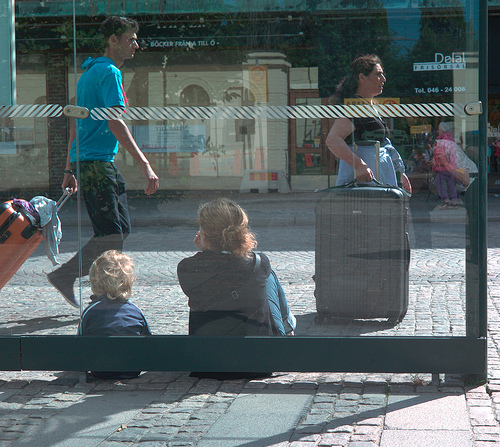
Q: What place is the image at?
A: It is at the street.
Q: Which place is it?
A: It is a street.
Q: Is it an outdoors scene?
A: Yes, it is outdoors.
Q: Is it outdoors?
A: Yes, it is outdoors.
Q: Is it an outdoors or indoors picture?
A: It is outdoors.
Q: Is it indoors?
A: No, it is outdoors.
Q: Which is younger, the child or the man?
A: The child is younger than the man.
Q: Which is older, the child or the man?
A: The man is older than the child.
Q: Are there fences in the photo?
A: No, there are no fences.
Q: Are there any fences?
A: No, there are no fences.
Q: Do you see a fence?
A: No, there are no fences.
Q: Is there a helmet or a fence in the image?
A: No, there are no fences or helmets.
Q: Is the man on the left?
A: Yes, the man is on the left of the image.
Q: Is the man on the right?
A: No, the man is on the left of the image.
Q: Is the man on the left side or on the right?
A: The man is on the left of the image.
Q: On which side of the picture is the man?
A: The man is on the left of the image.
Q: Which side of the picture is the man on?
A: The man is on the left of the image.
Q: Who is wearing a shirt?
A: The man is wearing a shirt.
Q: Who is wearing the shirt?
A: The man is wearing a shirt.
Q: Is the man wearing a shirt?
A: Yes, the man is wearing a shirt.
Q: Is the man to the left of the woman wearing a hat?
A: No, the man is wearing a shirt.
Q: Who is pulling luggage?
A: The man is pulling luggage.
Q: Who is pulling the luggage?
A: The man is pulling luggage.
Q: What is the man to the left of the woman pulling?
A: The man is pulling luggage.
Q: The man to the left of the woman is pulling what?
A: The man is pulling luggage.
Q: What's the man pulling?
A: The man is pulling luggage.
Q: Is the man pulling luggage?
A: Yes, the man is pulling luggage.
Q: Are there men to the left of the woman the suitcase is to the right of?
A: Yes, there is a man to the left of the woman.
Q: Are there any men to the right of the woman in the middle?
A: No, the man is to the left of the woman.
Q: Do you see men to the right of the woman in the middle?
A: No, the man is to the left of the woman.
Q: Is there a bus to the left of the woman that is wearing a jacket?
A: No, there is a man to the left of the woman.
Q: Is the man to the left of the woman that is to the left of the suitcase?
A: Yes, the man is to the left of the woman.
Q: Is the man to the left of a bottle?
A: No, the man is to the left of the woman.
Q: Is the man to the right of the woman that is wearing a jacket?
A: No, the man is to the left of the woman.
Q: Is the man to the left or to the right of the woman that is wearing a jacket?
A: The man is to the left of the woman.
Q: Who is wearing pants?
A: The man is wearing pants.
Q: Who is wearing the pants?
A: The man is wearing pants.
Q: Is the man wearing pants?
A: Yes, the man is wearing pants.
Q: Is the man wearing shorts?
A: No, the man is wearing pants.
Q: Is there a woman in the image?
A: Yes, there is a woman.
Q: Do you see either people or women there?
A: Yes, there is a woman.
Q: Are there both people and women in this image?
A: Yes, there are both a woman and people.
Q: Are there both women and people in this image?
A: Yes, there are both a woman and people.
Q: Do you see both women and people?
A: Yes, there are both a woman and people.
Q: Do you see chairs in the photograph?
A: No, there are no chairs.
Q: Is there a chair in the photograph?
A: No, there are no chairs.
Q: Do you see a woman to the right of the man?
A: Yes, there is a woman to the right of the man.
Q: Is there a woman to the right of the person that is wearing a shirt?
A: Yes, there is a woman to the right of the man.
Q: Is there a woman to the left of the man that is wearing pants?
A: No, the woman is to the right of the man.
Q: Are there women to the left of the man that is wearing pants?
A: No, the woman is to the right of the man.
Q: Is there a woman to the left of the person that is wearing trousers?
A: No, the woman is to the right of the man.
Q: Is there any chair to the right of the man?
A: No, there is a woman to the right of the man.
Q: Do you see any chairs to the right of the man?
A: No, there is a woman to the right of the man.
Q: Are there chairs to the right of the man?
A: No, there is a woman to the right of the man.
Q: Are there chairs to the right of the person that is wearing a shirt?
A: No, there is a woman to the right of the man.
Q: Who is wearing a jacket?
A: The woman is wearing a jacket.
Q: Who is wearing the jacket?
A: The woman is wearing a jacket.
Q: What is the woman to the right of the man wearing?
A: The woman is wearing a jacket.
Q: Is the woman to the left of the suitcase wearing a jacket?
A: Yes, the woman is wearing a jacket.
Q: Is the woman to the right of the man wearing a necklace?
A: No, the woman is wearing a jacket.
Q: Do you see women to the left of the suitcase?
A: Yes, there is a woman to the left of the suitcase.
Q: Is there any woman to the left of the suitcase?
A: Yes, there is a woman to the left of the suitcase.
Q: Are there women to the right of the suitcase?
A: No, the woman is to the left of the suitcase.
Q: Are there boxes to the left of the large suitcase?
A: No, there is a woman to the left of the suitcase.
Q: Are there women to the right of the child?
A: Yes, there is a woman to the right of the child.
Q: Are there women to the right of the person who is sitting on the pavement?
A: Yes, there is a woman to the right of the child.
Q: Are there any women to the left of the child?
A: No, the woman is to the right of the child.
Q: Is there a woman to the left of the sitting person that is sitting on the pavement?
A: No, the woman is to the right of the child.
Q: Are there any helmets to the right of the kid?
A: No, there is a woman to the right of the kid.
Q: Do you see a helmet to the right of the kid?
A: No, there is a woman to the right of the kid.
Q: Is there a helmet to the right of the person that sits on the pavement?
A: No, there is a woman to the right of the kid.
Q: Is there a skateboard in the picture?
A: No, there are no skateboards.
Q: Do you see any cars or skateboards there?
A: No, there are no skateboards or cars.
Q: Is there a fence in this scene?
A: No, there are no fences.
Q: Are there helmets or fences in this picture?
A: No, there are no fences or helmets.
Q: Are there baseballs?
A: No, there are no baseballs.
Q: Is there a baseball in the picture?
A: No, there are no baseballs.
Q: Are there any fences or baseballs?
A: No, there are no baseballs or fences.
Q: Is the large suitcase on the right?
A: Yes, the suitcase is on the right of the image.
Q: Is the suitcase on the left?
A: No, the suitcase is on the right of the image.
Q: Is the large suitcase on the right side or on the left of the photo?
A: The suitcase is on the right of the image.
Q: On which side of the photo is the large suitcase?
A: The suitcase is on the right of the image.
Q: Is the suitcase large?
A: Yes, the suitcase is large.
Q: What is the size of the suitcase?
A: The suitcase is large.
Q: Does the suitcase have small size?
A: No, the suitcase is large.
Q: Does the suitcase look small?
A: No, the suitcase is large.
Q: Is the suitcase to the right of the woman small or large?
A: The suitcase is large.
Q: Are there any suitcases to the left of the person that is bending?
A: Yes, there is a suitcase to the left of the person.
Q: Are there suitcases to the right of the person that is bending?
A: No, the suitcase is to the left of the person.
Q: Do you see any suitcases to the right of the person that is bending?
A: No, the suitcase is to the left of the person.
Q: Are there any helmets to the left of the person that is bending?
A: No, there is a suitcase to the left of the person.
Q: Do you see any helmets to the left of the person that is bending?
A: No, there is a suitcase to the left of the person.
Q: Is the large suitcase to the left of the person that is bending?
A: Yes, the suitcase is to the left of the person.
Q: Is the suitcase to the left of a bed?
A: No, the suitcase is to the left of the person.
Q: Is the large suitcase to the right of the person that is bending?
A: No, the suitcase is to the left of the person.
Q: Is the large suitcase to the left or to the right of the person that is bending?
A: The suitcase is to the left of the person.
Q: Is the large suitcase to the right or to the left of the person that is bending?
A: The suitcase is to the left of the person.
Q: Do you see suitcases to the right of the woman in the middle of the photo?
A: Yes, there is a suitcase to the right of the woman.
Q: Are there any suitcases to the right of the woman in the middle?
A: Yes, there is a suitcase to the right of the woman.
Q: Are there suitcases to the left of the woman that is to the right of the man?
A: No, the suitcase is to the right of the woman.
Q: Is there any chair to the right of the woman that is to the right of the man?
A: No, there is a suitcase to the right of the woman.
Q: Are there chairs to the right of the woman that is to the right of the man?
A: No, there is a suitcase to the right of the woman.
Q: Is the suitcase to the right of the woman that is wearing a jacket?
A: Yes, the suitcase is to the right of the woman.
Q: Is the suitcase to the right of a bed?
A: No, the suitcase is to the right of the woman.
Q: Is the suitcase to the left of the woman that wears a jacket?
A: No, the suitcase is to the right of the woman.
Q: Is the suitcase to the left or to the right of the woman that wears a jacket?
A: The suitcase is to the right of the woman.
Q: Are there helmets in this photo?
A: No, there are no helmets.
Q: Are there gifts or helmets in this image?
A: No, there are no helmets or gifts.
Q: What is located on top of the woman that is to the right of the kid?
A: The hair is on top of the woman.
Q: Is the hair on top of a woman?
A: Yes, the hair is on top of a woman.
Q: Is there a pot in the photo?
A: No, there are no pots.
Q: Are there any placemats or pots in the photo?
A: No, there are no pots or placemats.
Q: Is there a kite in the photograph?
A: No, there are no kites.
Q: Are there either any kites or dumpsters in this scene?
A: No, there are no kites or dumpsters.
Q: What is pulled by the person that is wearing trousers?
A: The luggage is pulled by the man.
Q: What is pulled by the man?
A: The luggage is pulled by the man.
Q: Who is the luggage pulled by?
A: The luggage is pulled by the man.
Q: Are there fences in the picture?
A: No, there are no fences.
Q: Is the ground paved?
A: Yes, the ground is paved.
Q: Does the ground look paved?
A: Yes, the ground is paved.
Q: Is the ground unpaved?
A: No, the ground is paved.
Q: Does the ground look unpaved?
A: No, the ground is paved.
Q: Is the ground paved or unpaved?
A: The ground is paved.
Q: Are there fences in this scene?
A: No, there are no fences.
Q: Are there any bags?
A: Yes, there is a bag.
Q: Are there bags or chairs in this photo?
A: Yes, there is a bag.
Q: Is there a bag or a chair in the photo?
A: Yes, there is a bag.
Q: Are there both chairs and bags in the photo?
A: No, there is a bag but no chairs.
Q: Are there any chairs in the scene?
A: No, there are no chairs.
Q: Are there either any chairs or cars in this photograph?
A: No, there are no chairs or cars.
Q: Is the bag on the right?
A: Yes, the bag is on the right of the image.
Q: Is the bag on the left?
A: No, the bag is on the right of the image.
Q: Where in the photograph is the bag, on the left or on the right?
A: The bag is on the right of the image.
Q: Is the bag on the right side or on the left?
A: The bag is on the right of the image.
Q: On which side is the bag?
A: The bag is on the right of the image.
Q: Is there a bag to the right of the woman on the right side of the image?
A: Yes, there is a bag to the right of the woman.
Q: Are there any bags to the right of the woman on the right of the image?
A: Yes, there is a bag to the right of the woman.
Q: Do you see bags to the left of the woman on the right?
A: No, the bag is to the right of the woman.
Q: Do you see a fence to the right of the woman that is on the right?
A: No, there is a bag to the right of the woman.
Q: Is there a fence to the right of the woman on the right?
A: No, there is a bag to the right of the woman.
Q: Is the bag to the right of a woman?
A: Yes, the bag is to the right of a woman.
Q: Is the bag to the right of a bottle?
A: No, the bag is to the right of a woman.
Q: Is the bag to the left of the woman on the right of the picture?
A: No, the bag is to the right of the woman.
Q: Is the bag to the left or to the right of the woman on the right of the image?
A: The bag is to the right of the woman.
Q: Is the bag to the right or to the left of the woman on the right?
A: The bag is to the right of the woman.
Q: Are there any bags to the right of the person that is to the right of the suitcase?
A: Yes, there is a bag to the right of the person.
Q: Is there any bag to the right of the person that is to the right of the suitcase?
A: Yes, there is a bag to the right of the person.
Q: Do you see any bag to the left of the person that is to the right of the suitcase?
A: No, the bag is to the right of the person.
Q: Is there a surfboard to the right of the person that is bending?
A: No, there is a bag to the right of the person.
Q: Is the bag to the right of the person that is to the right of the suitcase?
A: Yes, the bag is to the right of the person.